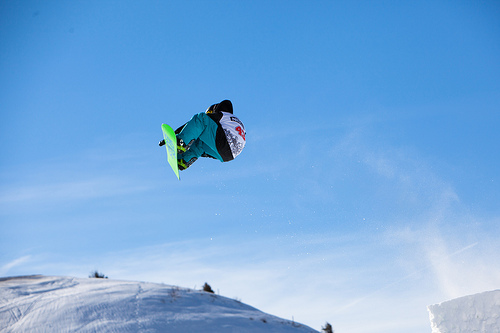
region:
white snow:
[51, 257, 132, 329]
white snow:
[77, 248, 171, 328]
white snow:
[78, 280, 153, 324]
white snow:
[15, 220, 150, 330]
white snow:
[42, 235, 116, 300]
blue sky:
[297, 48, 361, 116]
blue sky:
[281, 84, 402, 212]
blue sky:
[274, 14, 361, 155]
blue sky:
[285, 38, 336, 146]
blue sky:
[291, 82, 332, 162]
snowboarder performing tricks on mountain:
[156, 94, 254, 175]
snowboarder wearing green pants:
[188, 122, 211, 159]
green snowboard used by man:
[156, 125, 181, 184]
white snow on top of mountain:
[16, 286, 128, 327]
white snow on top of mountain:
[145, 303, 233, 325]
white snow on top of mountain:
[447, 308, 491, 327]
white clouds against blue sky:
[21, 17, 144, 164]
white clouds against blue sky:
[30, 152, 134, 249]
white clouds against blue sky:
[131, 185, 476, 265]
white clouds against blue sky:
[271, 25, 457, 275]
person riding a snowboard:
[145, 91, 260, 188]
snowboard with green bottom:
[156, 119, 183, 186]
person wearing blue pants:
[152, 91, 252, 176]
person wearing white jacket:
[152, 96, 249, 185]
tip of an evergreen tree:
[196, 280, 216, 297]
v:
[85, 263, 108, 284]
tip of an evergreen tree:
[320, 316, 339, 331]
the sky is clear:
[10, 3, 498, 270]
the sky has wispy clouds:
[10, 5, 498, 267]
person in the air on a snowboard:
[150, 95, 256, 187]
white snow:
[55, 278, 102, 302]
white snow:
[54, 278, 121, 313]